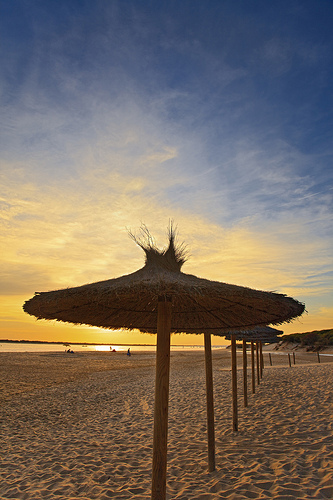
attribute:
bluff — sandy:
[256, 325, 332, 353]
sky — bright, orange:
[0, 0, 332, 214]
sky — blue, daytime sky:
[4, 8, 326, 206]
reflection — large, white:
[93, 344, 120, 350]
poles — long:
[125, 340, 294, 437]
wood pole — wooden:
[222, 328, 254, 438]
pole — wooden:
[203, 329, 217, 474]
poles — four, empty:
[143, 300, 176, 498]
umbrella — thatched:
[21, 219, 305, 332]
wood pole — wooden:
[149, 294, 174, 499]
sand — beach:
[253, 382, 317, 468]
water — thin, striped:
[11, 327, 43, 357]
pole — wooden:
[150, 299, 174, 499]